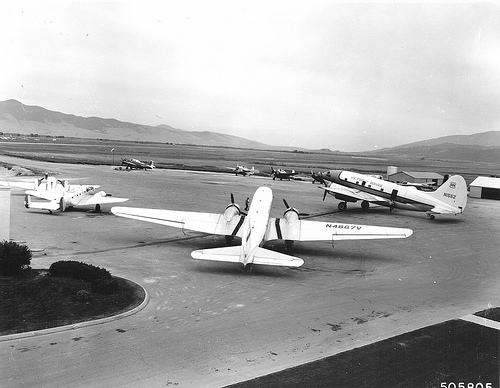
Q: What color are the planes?
A: White.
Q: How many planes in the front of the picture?
A: Three.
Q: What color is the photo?
A: Black and white.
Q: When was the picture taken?
A: Daytime.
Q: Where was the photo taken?
A: Airport.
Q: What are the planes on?
A: Ground.